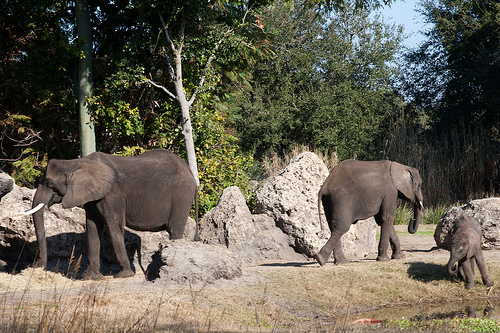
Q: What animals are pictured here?
A: Elephants.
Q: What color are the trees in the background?
A: Green.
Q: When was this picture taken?
A: Daytime.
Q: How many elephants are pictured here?
A: Three.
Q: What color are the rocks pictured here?
A: Grey.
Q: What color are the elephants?
A: Grey.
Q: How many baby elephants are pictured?
A: One.